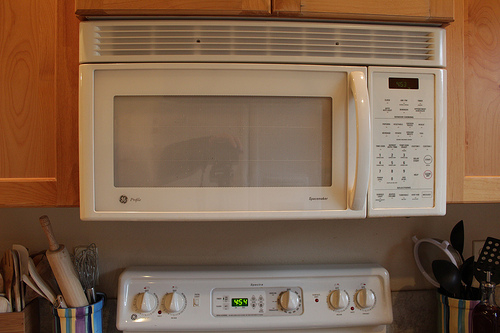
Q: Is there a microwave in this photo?
A: Yes, there is a microwave.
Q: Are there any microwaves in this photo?
A: Yes, there is a microwave.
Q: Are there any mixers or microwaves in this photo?
A: Yes, there is a microwave.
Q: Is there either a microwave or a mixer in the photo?
A: Yes, there is a microwave.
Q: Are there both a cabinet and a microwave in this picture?
A: Yes, there are both a microwave and a cabinet.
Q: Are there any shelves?
A: No, there are no shelves.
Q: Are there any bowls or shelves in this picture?
A: No, there are no shelves or bowls.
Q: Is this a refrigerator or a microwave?
A: This is a microwave.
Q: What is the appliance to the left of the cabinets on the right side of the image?
A: The appliance is a microwave.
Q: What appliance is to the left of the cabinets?
A: The appliance is a microwave.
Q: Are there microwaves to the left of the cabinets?
A: Yes, there is a microwave to the left of the cabinets.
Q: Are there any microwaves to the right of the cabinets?
A: No, the microwave is to the left of the cabinets.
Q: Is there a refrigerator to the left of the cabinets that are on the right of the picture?
A: No, there is a microwave to the left of the cabinets.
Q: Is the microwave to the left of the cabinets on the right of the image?
A: Yes, the microwave is to the left of the cabinets.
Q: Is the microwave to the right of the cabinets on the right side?
A: No, the microwave is to the left of the cabinets.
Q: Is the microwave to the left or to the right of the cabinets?
A: The microwave is to the left of the cabinets.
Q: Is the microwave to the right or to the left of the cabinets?
A: The microwave is to the left of the cabinets.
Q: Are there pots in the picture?
A: No, there are no pots.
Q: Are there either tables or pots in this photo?
A: No, there are no pots or tables.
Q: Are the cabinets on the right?
A: Yes, the cabinets are on the right of the image.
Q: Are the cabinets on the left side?
A: No, the cabinets are on the right of the image.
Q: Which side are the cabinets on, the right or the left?
A: The cabinets are on the right of the image.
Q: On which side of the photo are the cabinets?
A: The cabinets are on the right of the image.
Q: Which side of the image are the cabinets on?
A: The cabinets are on the right of the image.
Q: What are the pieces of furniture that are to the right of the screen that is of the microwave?
A: The pieces of furniture are cabinets.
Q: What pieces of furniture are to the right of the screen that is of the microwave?
A: The pieces of furniture are cabinets.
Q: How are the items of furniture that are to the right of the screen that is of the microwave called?
A: The pieces of furniture are cabinets.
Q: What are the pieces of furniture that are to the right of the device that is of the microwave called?
A: The pieces of furniture are cabinets.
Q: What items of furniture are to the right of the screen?
A: The pieces of furniture are cabinets.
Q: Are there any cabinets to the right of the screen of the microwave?
A: Yes, there are cabinets to the right of the screen.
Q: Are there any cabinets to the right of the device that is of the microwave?
A: Yes, there are cabinets to the right of the screen.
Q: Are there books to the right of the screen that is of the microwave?
A: No, there are cabinets to the right of the screen.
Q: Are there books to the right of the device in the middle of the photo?
A: No, there are cabinets to the right of the screen.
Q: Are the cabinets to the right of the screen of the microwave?
A: Yes, the cabinets are to the right of the screen.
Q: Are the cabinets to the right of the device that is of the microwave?
A: Yes, the cabinets are to the right of the screen.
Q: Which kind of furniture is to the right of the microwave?
A: The pieces of furniture are cabinets.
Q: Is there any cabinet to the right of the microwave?
A: Yes, there are cabinets to the right of the microwave.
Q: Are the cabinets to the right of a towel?
A: No, the cabinets are to the right of the microwave.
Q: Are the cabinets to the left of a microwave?
A: No, the cabinets are to the right of a microwave.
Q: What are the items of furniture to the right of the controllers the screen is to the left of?
A: The pieces of furniture are cabinets.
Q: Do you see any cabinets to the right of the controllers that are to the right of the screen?
A: Yes, there are cabinets to the right of the controllers.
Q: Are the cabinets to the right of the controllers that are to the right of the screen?
A: Yes, the cabinets are to the right of the controllers.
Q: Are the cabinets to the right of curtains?
A: No, the cabinets are to the right of the controllers.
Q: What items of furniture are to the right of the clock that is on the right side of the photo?
A: The pieces of furniture are cabinets.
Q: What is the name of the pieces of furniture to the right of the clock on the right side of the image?
A: The pieces of furniture are cabinets.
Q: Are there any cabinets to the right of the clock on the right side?
A: Yes, there are cabinets to the right of the clock.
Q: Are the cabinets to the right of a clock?
A: Yes, the cabinets are to the right of a clock.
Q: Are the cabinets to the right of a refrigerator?
A: No, the cabinets are to the right of a clock.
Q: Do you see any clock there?
A: Yes, there is a clock.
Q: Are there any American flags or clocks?
A: Yes, there is a clock.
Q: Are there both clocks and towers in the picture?
A: No, there is a clock but no towers.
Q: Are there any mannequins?
A: No, there are no mannequins.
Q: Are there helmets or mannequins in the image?
A: No, there are no mannequins or helmets.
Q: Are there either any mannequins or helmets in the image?
A: No, there are no mannequins or helmets.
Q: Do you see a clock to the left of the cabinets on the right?
A: Yes, there is a clock to the left of the cabinets.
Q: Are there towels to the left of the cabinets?
A: No, there is a clock to the left of the cabinets.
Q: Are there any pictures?
A: No, there are no pictures.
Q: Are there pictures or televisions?
A: No, there are no pictures or televisions.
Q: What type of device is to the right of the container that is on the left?
A: The devices are controllers.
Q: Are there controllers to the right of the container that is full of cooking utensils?
A: Yes, there are controllers to the right of the container.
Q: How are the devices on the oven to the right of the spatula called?
A: The devices are controllers.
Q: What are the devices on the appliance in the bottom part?
A: The devices are controllers.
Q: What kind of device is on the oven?
A: The devices are controllers.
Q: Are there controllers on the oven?
A: Yes, there are controllers on the oven.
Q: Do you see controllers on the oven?
A: Yes, there are controllers on the oven.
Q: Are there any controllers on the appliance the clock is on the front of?
A: Yes, there are controllers on the oven.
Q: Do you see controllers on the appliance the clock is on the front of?
A: Yes, there are controllers on the oven.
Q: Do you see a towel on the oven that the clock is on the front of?
A: No, there are controllers on the oven.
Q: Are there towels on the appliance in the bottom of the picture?
A: No, there are controllers on the oven.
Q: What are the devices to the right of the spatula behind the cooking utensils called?
A: The devices are controllers.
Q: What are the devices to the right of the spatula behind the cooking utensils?
A: The devices are controllers.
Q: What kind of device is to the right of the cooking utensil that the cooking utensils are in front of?
A: The devices are controllers.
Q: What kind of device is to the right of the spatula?
A: The devices are controllers.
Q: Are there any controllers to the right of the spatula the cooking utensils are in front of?
A: Yes, there are controllers to the right of the spatula.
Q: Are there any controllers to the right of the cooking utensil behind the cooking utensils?
A: Yes, there are controllers to the right of the spatula.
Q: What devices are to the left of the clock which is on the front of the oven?
A: The devices are controllers.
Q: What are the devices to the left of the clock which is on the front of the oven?
A: The devices are controllers.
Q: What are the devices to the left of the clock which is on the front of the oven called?
A: The devices are controllers.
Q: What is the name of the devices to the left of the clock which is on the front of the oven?
A: The devices are controllers.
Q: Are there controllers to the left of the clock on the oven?
A: Yes, there are controllers to the left of the clock.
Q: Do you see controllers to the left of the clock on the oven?
A: Yes, there are controllers to the left of the clock.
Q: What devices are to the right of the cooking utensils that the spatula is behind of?
A: The devices are controllers.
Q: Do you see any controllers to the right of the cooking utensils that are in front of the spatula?
A: Yes, there are controllers to the right of the cooking utensils.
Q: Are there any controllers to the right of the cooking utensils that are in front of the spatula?
A: Yes, there are controllers to the right of the cooking utensils.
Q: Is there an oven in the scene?
A: Yes, there is an oven.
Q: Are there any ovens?
A: Yes, there is an oven.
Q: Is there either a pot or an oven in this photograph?
A: Yes, there is an oven.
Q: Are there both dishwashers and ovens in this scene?
A: No, there is an oven but no dishwashers.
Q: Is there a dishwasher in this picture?
A: No, there are no dishwashers.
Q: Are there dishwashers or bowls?
A: No, there are no dishwashers or bowls.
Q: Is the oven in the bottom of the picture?
A: Yes, the oven is in the bottom of the image.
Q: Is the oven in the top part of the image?
A: No, the oven is in the bottom of the image.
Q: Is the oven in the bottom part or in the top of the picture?
A: The oven is in the bottom of the image.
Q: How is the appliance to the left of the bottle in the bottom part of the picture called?
A: The appliance is an oven.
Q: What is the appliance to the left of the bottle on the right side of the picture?
A: The appliance is an oven.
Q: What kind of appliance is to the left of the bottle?
A: The appliance is an oven.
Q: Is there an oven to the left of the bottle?
A: Yes, there is an oven to the left of the bottle.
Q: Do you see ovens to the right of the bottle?
A: No, the oven is to the left of the bottle.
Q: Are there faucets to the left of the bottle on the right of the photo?
A: No, there is an oven to the left of the bottle.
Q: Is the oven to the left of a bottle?
A: Yes, the oven is to the left of a bottle.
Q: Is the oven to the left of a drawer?
A: No, the oven is to the left of a bottle.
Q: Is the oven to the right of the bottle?
A: No, the oven is to the left of the bottle.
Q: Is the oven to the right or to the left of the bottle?
A: The oven is to the left of the bottle.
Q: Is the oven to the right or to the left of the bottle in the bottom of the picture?
A: The oven is to the left of the bottle.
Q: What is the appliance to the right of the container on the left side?
A: The appliance is an oven.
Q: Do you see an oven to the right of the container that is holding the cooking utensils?
A: Yes, there is an oven to the right of the container.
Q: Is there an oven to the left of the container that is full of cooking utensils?
A: No, the oven is to the right of the container.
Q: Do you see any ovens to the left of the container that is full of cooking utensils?
A: No, the oven is to the right of the container.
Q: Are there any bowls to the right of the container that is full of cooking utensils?
A: No, there is an oven to the right of the container.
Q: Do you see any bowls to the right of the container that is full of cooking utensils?
A: No, there is an oven to the right of the container.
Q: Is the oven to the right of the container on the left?
A: Yes, the oven is to the right of the container.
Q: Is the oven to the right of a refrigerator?
A: No, the oven is to the right of the container.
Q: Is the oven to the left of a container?
A: No, the oven is to the right of a container.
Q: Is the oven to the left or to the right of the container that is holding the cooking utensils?
A: The oven is to the right of the container.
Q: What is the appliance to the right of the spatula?
A: The appliance is an oven.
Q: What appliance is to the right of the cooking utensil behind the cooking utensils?
A: The appliance is an oven.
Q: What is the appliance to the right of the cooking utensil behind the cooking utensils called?
A: The appliance is an oven.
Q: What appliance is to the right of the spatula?
A: The appliance is an oven.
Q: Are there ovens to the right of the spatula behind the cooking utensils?
A: Yes, there is an oven to the right of the spatula.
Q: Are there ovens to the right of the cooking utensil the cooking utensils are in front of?
A: Yes, there is an oven to the right of the spatula.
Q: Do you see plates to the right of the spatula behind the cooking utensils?
A: No, there is an oven to the right of the spatula.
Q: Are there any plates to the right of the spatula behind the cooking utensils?
A: No, there is an oven to the right of the spatula.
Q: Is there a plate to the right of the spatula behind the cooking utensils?
A: No, there is an oven to the right of the spatula.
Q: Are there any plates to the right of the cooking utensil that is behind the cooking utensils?
A: No, there is an oven to the right of the spatula.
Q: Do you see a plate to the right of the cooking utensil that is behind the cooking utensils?
A: No, there is an oven to the right of the spatula.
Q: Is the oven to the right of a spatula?
A: Yes, the oven is to the right of a spatula.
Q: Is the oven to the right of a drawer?
A: No, the oven is to the right of a spatula.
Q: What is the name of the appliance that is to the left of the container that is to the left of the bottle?
A: The appliance is an oven.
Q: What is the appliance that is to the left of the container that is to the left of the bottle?
A: The appliance is an oven.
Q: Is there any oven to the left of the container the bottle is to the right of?
A: Yes, there is an oven to the left of the container.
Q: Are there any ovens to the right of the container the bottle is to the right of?
A: No, the oven is to the left of the container.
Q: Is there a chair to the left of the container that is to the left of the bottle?
A: No, there is an oven to the left of the container.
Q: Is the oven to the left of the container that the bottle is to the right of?
A: Yes, the oven is to the left of the container.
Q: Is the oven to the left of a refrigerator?
A: No, the oven is to the left of the container.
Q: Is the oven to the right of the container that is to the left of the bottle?
A: No, the oven is to the left of the container.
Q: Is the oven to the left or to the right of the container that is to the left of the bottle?
A: The oven is to the left of the container.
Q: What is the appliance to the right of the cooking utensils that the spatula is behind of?
A: The appliance is an oven.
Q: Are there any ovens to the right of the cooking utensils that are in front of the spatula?
A: Yes, there is an oven to the right of the cooking utensils.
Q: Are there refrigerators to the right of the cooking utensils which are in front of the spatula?
A: No, there is an oven to the right of the cooking utensils.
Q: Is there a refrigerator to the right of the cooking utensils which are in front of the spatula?
A: No, there is an oven to the right of the cooking utensils.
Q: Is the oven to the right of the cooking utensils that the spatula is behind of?
A: Yes, the oven is to the right of the cooking utensils.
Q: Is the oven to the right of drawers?
A: No, the oven is to the right of the cooking utensils.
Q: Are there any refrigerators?
A: No, there are no refrigerators.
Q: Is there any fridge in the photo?
A: No, there are no refrigerators.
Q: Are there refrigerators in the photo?
A: No, there are no refrigerators.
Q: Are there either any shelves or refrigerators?
A: No, there are no refrigerators or shelves.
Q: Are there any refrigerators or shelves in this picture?
A: No, there are no refrigerators or shelves.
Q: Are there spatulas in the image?
A: Yes, there is a spatula.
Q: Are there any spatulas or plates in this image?
A: Yes, there is a spatula.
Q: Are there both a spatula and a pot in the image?
A: No, there is a spatula but no pots.